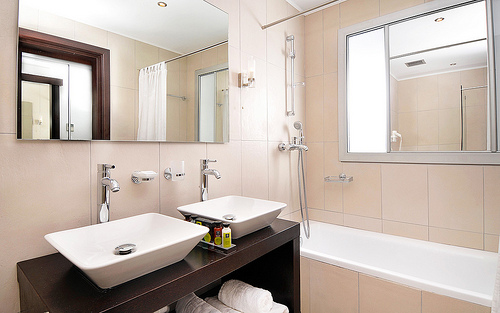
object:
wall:
[0, 0, 322, 235]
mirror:
[16, 1, 233, 140]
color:
[39, 211, 210, 289]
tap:
[93, 160, 120, 226]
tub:
[296, 209, 499, 312]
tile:
[221, 145, 272, 185]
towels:
[215, 280, 273, 313]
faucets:
[93, 159, 121, 221]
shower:
[279, 32, 312, 244]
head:
[290, 119, 307, 140]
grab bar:
[320, 171, 355, 185]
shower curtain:
[138, 64, 168, 144]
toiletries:
[218, 221, 233, 249]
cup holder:
[163, 159, 188, 182]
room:
[5, 4, 498, 309]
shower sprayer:
[289, 119, 308, 157]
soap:
[131, 170, 160, 184]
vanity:
[12, 221, 306, 307]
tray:
[186, 238, 237, 255]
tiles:
[427, 167, 485, 226]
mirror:
[344, 1, 497, 154]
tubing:
[297, 133, 318, 245]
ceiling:
[26, 0, 231, 55]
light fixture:
[152, 1, 168, 11]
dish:
[134, 171, 154, 184]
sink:
[176, 193, 288, 240]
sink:
[44, 210, 210, 289]